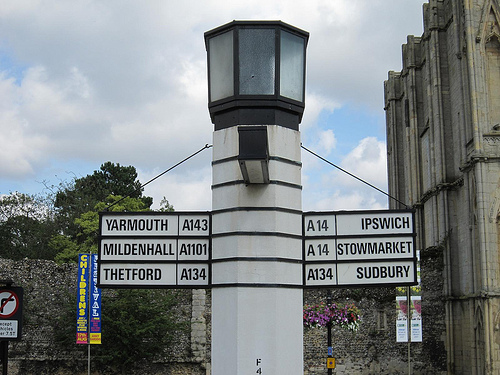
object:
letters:
[103, 218, 413, 281]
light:
[204, 19, 311, 125]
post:
[208, 124, 303, 375]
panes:
[207, 32, 241, 101]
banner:
[76, 252, 104, 345]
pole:
[87, 344, 91, 375]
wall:
[3, 257, 396, 375]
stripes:
[211, 178, 307, 288]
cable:
[298, 144, 411, 207]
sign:
[99, 211, 416, 286]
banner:
[396, 296, 424, 344]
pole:
[405, 285, 411, 374]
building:
[383, 0, 500, 375]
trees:
[3, 162, 179, 259]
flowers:
[299, 301, 355, 327]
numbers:
[180, 218, 335, 281]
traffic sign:
[0, 287, 24, 343]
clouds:
[1, 1, 404, 208]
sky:
[0, 3, 426, 219]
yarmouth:
[106, 218, 170, 232]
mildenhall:
[100, 240, 177, 261]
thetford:
[103, 268, 162, 280]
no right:
[1, 291, 19, 320]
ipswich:
[360, 217, 411, 229]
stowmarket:
[337, 240, 413, 254]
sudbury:
[356, 265, 410, 279]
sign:
[328, 358, 336, 368]